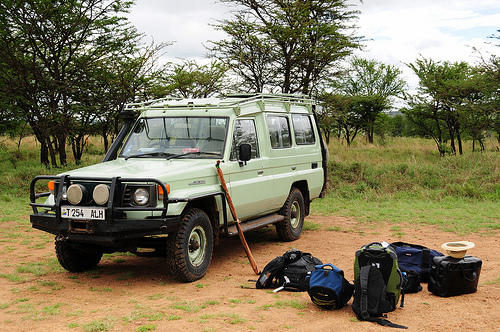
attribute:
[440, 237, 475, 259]
straw hat — straw , Tan 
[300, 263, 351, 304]
back pack — black , blue 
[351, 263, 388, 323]
backpack — black , grey 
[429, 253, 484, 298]
luggage bag — black , luggage 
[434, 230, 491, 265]
hat — Tan 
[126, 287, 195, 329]
grass — patches 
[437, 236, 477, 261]
hat — Tan 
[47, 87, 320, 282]
jeep — light green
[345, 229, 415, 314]
backpack — green, black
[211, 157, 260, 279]
umbrella — long , orange 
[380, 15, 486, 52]
cloudy sky — blue 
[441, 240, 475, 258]
hat — vanilla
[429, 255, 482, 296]
bag — black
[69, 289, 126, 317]
dirt — patches 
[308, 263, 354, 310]
backpack — blue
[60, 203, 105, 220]
license plate — license 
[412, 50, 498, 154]
tree — green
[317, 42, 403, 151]
tree — green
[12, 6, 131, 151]
tree — green